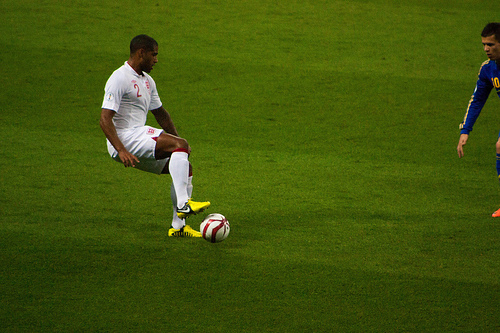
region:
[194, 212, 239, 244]
a soccer ball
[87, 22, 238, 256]
man playing in a game of soccer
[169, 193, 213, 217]
yellow soccer shoes with Nike swsh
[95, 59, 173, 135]
a white soccer jersey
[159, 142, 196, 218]
white soccer socks and shin guards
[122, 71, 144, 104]
the number two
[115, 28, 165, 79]
man's face in profile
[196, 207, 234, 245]
red and white soccer ball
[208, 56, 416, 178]
grass on a soccer field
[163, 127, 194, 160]
knee at 90 degree angle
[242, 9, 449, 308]
thick green lawn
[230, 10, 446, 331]
green grass soccer field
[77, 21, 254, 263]
Soccer player with dark skin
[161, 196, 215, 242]
yellow, white, and black soccer cleats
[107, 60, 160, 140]
short sleeve white shorts uniform shirt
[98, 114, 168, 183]
white soccer uniform shorts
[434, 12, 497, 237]
soccer player wearing blue shirt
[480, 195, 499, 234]
orange soccer cleat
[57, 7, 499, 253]
two young men playing soccer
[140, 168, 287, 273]
the shoes is yellow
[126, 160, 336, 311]
the shoe is yellow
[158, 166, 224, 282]
the shoe is yellow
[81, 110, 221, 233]
the shoe is yellow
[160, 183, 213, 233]
the shoe is yellow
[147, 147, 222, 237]
the shoe is yellow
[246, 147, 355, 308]
the grass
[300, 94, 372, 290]
the grass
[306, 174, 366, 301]
the grass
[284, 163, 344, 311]
the grass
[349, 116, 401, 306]
the grass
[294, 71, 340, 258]
the grass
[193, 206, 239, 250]
The ball is round.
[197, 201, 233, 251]
The ball is white.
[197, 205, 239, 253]
Ball has red stripes.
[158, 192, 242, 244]
The shoes are yellow.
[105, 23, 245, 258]
Man is wearing shoes.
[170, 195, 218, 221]
The has cleats on bottom.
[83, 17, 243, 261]
Man is wearing socks.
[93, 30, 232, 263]
The socks are white.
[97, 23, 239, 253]
Man is wearing shorts.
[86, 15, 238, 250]
The man has hair.